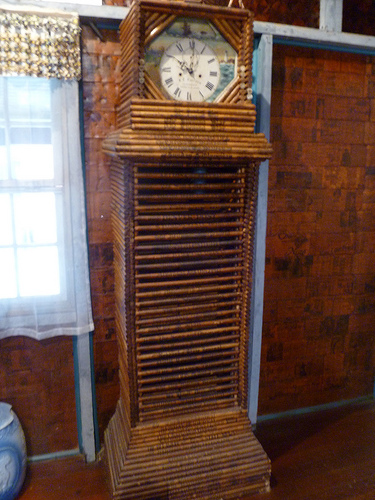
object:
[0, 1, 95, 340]
curtain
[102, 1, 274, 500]
clock holder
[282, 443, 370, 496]
floor sheet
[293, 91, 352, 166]
tiles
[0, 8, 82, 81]
baseball cap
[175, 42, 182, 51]
roman numerals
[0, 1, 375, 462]
brown wall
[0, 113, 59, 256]
window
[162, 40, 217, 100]
numerals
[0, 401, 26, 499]
pot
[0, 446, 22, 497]
designs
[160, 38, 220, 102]
clock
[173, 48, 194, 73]
hands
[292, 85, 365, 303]
cork wall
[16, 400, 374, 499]
floor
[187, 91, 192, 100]
roman numeral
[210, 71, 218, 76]
roman numeral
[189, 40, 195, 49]
roman numeral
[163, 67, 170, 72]
roman numeral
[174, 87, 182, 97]
roman numeral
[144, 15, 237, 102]
clock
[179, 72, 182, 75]
key hole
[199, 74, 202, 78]
key hole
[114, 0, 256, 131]
wallclock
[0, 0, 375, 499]
photo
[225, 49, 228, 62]
light house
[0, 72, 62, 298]
pane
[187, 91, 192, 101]
vi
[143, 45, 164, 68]
design